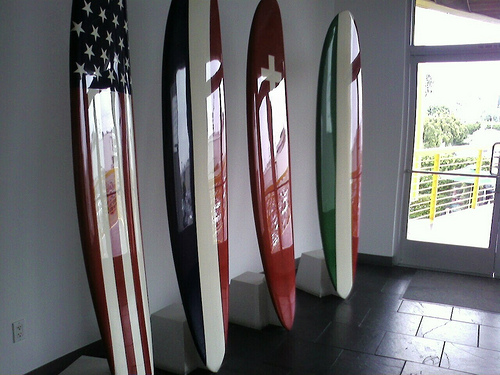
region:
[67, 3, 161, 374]
Surfboard with American flag graphic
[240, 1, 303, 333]
Surfboard with Swiss flag graphic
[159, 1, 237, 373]
Surfboard with French flag graphic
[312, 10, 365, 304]
Surfboard with Italian flag graphic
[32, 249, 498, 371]
Grey square tiled floor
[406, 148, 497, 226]
Yellow guard rail outside doorway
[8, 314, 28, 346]
White electrical outlet on wall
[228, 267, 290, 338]
White box holding surfboard display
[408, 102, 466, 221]
Green tree outside display room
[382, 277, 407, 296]
grey tile on floor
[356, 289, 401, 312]
grey tile on floor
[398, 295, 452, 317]
grey tile on floor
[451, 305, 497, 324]
grey tile on floor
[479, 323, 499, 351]
grey tile on floor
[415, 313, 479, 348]
grey tile on floor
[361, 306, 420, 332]
grey tile on floor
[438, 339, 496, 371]
grey tile on floor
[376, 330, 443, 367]
grey tile on floor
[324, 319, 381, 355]
grey tile on floor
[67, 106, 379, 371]
SURFBOARDS LEANING AGAINST WALL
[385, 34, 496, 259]
DOOR LEADING OUTSIDE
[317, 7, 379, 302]
SURFBOARD IS RED, WHITE AND GREEN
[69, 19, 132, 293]
SURFBOARD HAS U.S. FLAG DESIGN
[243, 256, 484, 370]
FLOOR IS TILED WITH BLACK TILE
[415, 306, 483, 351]
TILE IS SQUARE IN SHAPE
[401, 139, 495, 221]
RAILING ACROSS CEMENT SURFACE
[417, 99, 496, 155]
TREES SEEN IN DISTANCE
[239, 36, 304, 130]
CROSS DESIGN ON SURFBOARD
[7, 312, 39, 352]
ELECTRICAL OUTLET ON WALL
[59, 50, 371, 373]
Four surf boards against the wall.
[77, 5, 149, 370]
Surf board on the left has the US flag printed on it.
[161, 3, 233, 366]
The second surf board has red, white and blue on it.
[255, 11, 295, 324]
The third board has a cross on it.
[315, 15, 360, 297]
The last surf board is green white and red.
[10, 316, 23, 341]
A plug-in is on the wall.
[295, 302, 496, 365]
The tile is a deep brown.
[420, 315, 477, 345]
A crack in one of the tiles.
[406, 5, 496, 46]
Window over the door.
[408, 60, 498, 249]
The door is made of glass.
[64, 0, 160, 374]
A surfboard with an American flag theme.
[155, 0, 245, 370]
A red, white and blue surfboard.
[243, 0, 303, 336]
A red surfboard which has a white cross.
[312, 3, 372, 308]
A green, white and red striped surfboard.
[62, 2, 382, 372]
Four shiney, new surfboards.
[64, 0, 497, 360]
Four surfboards stand guard beside the door.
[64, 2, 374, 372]
Four surfboards reflect the outdoors.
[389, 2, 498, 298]
A glass and metal door.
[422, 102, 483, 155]
A green bush glows yellow.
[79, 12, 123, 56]
White stars on navy.